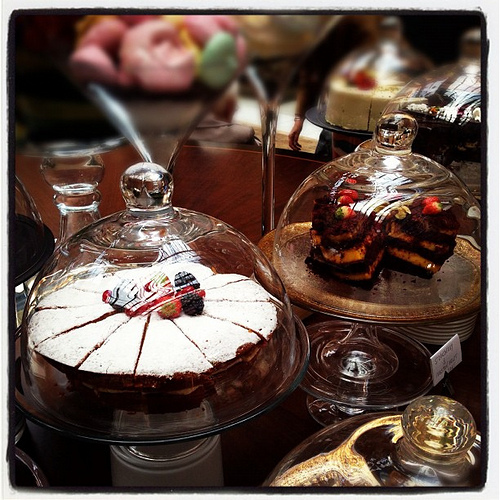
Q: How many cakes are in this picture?
A: Two.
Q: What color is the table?
A: Brown.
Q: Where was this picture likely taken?
A: A restaurant.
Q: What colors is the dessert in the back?
A: Pink, Green and Yellow.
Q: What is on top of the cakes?
A: Glass.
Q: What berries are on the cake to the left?
A: Raspberries and Blackberries.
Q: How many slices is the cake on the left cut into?
A: Twelve.